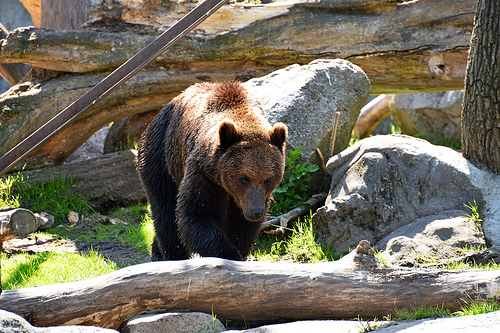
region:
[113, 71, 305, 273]
a bear is in between the logs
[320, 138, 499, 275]
a big rock is on the right side of the bear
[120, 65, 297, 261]
the bear is covered in brown fur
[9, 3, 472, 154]
some logs are piled up behind the bear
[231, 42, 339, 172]
the boulder is behind the bear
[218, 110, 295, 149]
the bear has it's ears perked up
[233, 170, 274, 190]
the bear has it's eyes open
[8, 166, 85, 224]
some green grass is up against the logs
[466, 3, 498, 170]
a tree stands to the right of the bear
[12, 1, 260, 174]
a metal railing is set in front of the pile of logs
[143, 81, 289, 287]
brown bear in zoo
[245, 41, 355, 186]
large boulder in pen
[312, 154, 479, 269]
large boulder in pen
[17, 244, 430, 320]
wood log by bear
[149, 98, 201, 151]
brown fur on large bear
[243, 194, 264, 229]
black nose on brown bear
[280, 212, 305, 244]
grass growing on ground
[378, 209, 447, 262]
sun shining on rocks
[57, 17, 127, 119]
metal rail over bear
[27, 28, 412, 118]
log in background behind bear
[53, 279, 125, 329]
a log on the ground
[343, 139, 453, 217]
a stone lying on the ground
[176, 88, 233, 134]
the bears fur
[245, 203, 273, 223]
the bear's nose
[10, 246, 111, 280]
the grass on the ground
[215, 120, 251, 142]
the bears ear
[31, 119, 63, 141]
a metal bar beside the bear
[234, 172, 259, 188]
the eye of a bear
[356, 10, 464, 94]
the logs of trees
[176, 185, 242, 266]
the front leg of a bear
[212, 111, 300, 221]
head of a bear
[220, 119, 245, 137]
ear of a bear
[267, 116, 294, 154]
ear of a bear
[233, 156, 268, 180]
eye of a bear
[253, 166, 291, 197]
eye of a bear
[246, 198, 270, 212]
nose of a bear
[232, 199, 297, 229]
mouth of a bear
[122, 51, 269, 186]
body of a bear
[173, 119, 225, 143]
fur of a bear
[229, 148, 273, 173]
forehead of a bear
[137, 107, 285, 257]
A bear walking on fours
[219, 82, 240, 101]
Tuft of hair sticking out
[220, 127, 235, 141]
Shadow on the ear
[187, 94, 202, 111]
Light shining on the coat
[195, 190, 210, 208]
Pieces of dirt on the fur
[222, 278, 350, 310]
A log lying across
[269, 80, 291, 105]
Reflection on a rock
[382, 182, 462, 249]
A rock on the ground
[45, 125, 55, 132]
An iron bar standing diagonally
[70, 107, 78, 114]
Rust on an iron bar